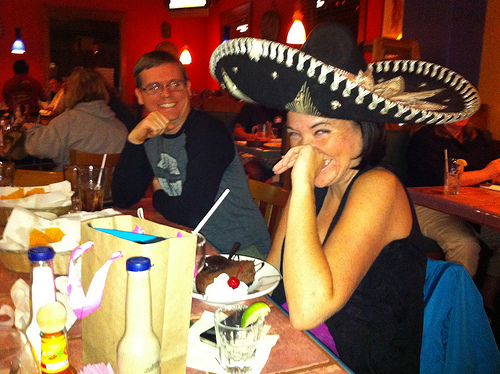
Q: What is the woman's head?
A: A sombrero.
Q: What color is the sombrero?
A: Black and silver.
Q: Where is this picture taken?
A: A restaurant.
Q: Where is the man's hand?
A: On his chin.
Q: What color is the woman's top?
A: Black.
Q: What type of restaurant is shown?
A: Mexican.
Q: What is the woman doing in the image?
A: Smiling.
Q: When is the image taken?
A: When the woman is smiling.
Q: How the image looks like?
A: Good.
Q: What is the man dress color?
A: Grey and black.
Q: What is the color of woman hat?
A: Black.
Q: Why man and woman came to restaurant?
A: Have food.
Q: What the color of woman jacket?
A: Blue.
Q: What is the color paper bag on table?
A: Yellow.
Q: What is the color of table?
A: Brown.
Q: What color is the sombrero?
A: Black and white.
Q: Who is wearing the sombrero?
A: A woman.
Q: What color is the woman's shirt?
A: Black.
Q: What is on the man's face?
A: Eyeglasses.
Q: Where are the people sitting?
A: At tables.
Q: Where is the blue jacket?
A: On the back of the chair.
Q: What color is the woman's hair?
A: Black.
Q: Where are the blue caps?
A: On the bottles on the table.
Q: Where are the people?
A: In a restaurant.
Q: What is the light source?
A: Overhead lights.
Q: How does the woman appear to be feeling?
A: Happy.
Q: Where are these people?
A: At a restaurant.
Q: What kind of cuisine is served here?
A: Mexican.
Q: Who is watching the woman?
A: The man wearing glasses.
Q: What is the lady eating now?
A: Dessert.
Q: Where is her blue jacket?
A: On the back of her chair.